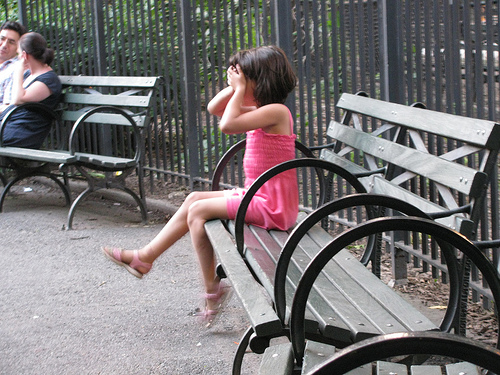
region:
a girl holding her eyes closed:
[204, 40, 301, 154]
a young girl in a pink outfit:
[177, 24, 321, 261]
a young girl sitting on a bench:
[176, 42, 498, 317]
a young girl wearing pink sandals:
[95, 45, 300, 332]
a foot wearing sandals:
[93, 240, 158, 288]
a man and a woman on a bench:
[3, 10, 144, 225]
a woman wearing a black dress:
[3, 35, 58, 152]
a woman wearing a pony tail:
[12, 31, 58, 77]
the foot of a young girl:
[101, 240, 158, 284]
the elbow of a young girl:
[218, 122, 235, 134]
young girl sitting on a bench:
[110, 42, 325, 324]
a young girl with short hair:
[226, 44, 302, 119]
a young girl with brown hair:
[225, 22, 302, 112]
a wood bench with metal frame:
[215, 115, 487, 346]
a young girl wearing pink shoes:
[107, 50, 283, 272]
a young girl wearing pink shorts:
[223, 85, 296, 241]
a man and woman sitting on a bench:
[0, 15, 71, 127]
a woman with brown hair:
[10, 25, 57, 88]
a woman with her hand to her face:
[7, 23, 40, 95]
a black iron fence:
[123, 5, 258, 143]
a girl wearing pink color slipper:
[97, 240, 164, 287]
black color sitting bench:
[188, 132, 473, 372]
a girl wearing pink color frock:
[221, 97, 308, 224]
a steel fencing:
[128, 16, 493, 167]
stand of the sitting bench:
[9, 153, 146, 233]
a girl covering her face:
[210, 55, 305, 136]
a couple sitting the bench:
[0, 13, 61, 210]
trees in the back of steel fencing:
[127, 16, 428, 133]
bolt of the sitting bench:
[452, 175, 474, 188]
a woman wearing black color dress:
[6, 70, 59, 149]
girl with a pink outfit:
[87, 39, 301, 332]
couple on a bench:
[0, 15, 64, 170]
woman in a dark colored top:
[4, 33, 64, 164]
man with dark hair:
[1, 17, 28, 119]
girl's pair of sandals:
[94, 238, 238, 340]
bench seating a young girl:
[181, 79, 491, 346]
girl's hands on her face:
[220, 64, 250, 109]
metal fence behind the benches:
[1, 0, 495, 302]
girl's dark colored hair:
[226, 38, 302, 111]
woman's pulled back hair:
[19, 30, 60, 67]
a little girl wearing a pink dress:
[95, 36, 307, 340]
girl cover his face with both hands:
[192, 38, 306, 156]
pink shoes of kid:
[91, 229, 233, 334]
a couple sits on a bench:
[1, 23, 162, 235]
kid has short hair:
[202, 39, 316, 149]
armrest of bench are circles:
[198, 131, 455, 358]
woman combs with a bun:
[1, 28, 76, 153]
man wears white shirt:
[1, 22, 26, 123]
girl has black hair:
[197, 41, 311, 142]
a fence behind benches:
[41, 8, 489, 296]